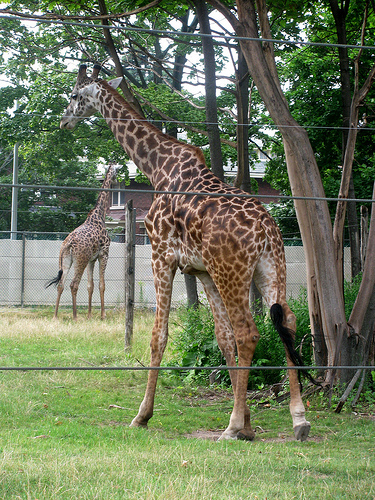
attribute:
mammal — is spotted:
[53, 56, 319, 443]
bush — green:
[167, 295, 318, 398]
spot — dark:
[226, 273, 233, 283]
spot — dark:
[235, 279, 243, 287]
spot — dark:
[226, 283, 231, 289]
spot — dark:
[221, 276, 228, 285]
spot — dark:
[233, 275, 240, 283]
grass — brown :
[4, 309, 133, 336]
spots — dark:
[99, 85, 300, 359]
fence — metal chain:
[0, 217, 162, 316]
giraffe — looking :
[49, 53, 312, 426]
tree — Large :
[194, 5, 374, 425]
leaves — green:
[294, 55, 338, 97]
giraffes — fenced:
[58, 61, 313, 444]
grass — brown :
[23, 394, 374, 495]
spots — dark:
[157, 282, 168, 329]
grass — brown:
[0, 308, 374, 498]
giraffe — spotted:
[31, 49, 301, 320]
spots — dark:
[197, 200, 224, 218]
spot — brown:
[227, 219, 237, 232]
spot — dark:
[172, 207, 189, 218]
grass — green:
[6, 451, 370, 494]